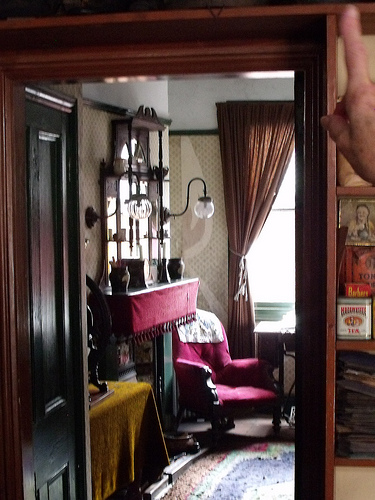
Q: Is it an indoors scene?
A: Yes, it is indoors.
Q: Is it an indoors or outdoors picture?
A: It is indoors.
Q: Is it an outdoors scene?
A: No, it is indoors.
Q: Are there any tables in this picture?
A: Yes, there is a table.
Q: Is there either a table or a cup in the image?
A: Yes, there is a table.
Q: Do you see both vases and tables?
A: Yes, there are both a table and a vase.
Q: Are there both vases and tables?
A: Yes, there are both a table and a vase.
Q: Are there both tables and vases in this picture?
A: Yes, there are both a table and a vase.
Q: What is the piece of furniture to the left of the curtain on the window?
A: The piece of furniture is a table.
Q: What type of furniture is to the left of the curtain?
A: The piece of furniture is a table.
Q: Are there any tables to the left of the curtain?
A: Yes, there is a table to the left of the curtain.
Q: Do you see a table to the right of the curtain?
A: No, the table is to the left of the curtain.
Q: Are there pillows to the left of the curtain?
A: No, there is a table to the left of the curtain.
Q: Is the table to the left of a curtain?
A: Yes, the table is to the left of a curtain.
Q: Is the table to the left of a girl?
A: No, the table is to the left of a curtain.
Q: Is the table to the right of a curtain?
A: No, the table is to the left of a curtain.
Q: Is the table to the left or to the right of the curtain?
A: The table is to the left of the curtain.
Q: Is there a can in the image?
A: No, there are no cans.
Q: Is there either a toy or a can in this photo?
A: No, there are no cans or toys.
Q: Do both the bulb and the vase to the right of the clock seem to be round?
A: Yes, both the bulb and the vase are round.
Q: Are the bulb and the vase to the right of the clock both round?
A: Yes, both the bulb and the vase are round.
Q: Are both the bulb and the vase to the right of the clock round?
A: Yes, both the bulb and the vase are round.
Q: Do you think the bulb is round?
A: Yes, the bulb is round.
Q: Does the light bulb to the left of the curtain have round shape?
A: Yes, the light bulb is round.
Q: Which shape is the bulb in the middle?
A: The light bulb is round.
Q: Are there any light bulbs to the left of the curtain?
A: Yes, there is a light bulb to the left of the curtain.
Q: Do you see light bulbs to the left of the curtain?
A: Yes, there is a light bulb to the left of the curtain.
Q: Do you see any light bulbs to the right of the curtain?
A: No, the light bulb is to the left of the curtain.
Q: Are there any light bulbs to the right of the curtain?
A: No, the light bulb is to the left of the curtain.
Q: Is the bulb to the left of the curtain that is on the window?
A: Yes, the bulb is to the left of the curtain.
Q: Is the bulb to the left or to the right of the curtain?
A: The bulb is to the left of the curtain.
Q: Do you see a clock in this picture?
A: Yes, there is a clock.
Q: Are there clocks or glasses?
A: Yes, there is a clock.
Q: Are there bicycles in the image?
A: No, there are no bicycles.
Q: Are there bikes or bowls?
A: No, there are no bikes or bowls.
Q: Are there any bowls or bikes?
A: No, there are no bikes or bowls.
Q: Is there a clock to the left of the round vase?
A: Yes, there is a clock to the left of the vase.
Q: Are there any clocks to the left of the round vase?
A: Yes, there is a clock to the left of the vase.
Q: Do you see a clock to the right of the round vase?
A: No, the clock is to the left of the vase.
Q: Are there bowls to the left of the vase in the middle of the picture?
A: No, there is a clock to the left of the vase.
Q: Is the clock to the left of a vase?
A: Yes, the clock is to the left of a vase.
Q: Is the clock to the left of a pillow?
A: No, the clock is to the left of a vase.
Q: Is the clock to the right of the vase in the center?
A: No, the clock is to the left of the vase.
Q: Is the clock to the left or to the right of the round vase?
A: The clock is to the left of the vase.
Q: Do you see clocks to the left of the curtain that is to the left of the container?
A: Yes, there is a clock to the left of the curtain.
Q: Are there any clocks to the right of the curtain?
A: No, the clock is to the left of the curtain.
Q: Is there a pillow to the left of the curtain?
A: No, there is a clock to the left of the curtain.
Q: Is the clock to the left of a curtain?
A: Yes, the clock is to the left of a curtain.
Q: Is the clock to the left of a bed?
A: No, the clock is to the left of a curtain.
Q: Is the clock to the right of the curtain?
A: No, the clock is to the left of the curtain.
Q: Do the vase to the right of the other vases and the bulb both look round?
A: Yes, both the vase and the bulb are round.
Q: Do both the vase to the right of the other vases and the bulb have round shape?
A: Yes, both the vase and the bulb are round.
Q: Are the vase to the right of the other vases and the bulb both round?
A: Yes, both the vase and the bulb are round.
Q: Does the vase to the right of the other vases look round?
A: Yes, the vase is round.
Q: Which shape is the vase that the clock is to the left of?
A: The vase is round.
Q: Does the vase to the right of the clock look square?
A: No, the vase is round.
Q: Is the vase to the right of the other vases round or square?
A: The vase is round.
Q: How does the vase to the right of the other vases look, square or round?
A: The vase is round.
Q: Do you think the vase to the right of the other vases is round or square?
A: The vase is round.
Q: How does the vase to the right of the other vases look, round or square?
A: The vase is round.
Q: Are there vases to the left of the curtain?
A: Yes, there is a vase to the left of the curtain.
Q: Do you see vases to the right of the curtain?
A: No, the vase is to the left of the curtain.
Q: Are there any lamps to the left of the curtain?
A: No, there is a vase to the left of the curtain.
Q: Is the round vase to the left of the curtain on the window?
A: Yes, the vase is to the left of the curtain.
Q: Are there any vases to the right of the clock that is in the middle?
A: Yes, there is a vase to the right of the clock.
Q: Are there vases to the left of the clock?
A: No, the vase is to the right of the clock.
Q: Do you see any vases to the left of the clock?
A: No, the vase is to the right of the clock.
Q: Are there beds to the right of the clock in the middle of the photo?
A: No, there is a vase to the right of the clock.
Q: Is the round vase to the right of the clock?
A: Yes, the vase is to the right of the clock.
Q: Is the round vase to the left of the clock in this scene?
A: No, the vase is to the right of the clock.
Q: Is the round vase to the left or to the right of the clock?
A: The vase is to the right of the clock.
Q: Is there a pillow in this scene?
A: No, there are no pillows.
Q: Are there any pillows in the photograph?
A: No, there are no pillows.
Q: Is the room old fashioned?
A: Yes, the room is old fashioned.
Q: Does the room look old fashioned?
A: Yes, the room is old fashioned.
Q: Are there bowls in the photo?
A: No, there are no bowls.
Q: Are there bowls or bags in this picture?
A: No, there are no bowls or bags.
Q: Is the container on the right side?
A: Yes, the container is on the right of the image.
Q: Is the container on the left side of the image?
A: No, the container is on the right of the image.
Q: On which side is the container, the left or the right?
A: The container is on the right of the image.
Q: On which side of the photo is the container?
A: The container is on the right of the image.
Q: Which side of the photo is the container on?
A: The container is on the right of the image.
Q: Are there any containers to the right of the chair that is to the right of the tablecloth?
A: Yes, there is a container to the right of the chair.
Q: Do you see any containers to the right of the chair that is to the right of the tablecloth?
A: Yes, there is a container to the right of the chair.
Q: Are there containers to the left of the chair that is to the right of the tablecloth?
A: No, the container is to the right of the chair.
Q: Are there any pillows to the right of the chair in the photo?
A: No, there is a container to the right of the chair.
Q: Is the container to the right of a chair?
A: Yes, the container is to the right of a chair.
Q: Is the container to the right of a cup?
A: No, the container is to the right of a chair.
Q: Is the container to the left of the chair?
A: No, the container is to the right of the chair.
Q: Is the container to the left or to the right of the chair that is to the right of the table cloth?
A: The container is to the right of the chair.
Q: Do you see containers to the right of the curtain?
A: Yes, there is a container to the right of the curtain.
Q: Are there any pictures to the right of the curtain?
A: No, there is a container to the right of the curtain.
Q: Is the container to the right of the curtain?
A: Yes, the container is to the right of the curtain.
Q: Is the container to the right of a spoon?
A: No, the container is to the right of the curtain.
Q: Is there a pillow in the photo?
A: No, there are no pillows.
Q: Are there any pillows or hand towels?
A: No, there are no pillows or hand towels.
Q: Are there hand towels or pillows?
A: No, there are no pillows or hand towels.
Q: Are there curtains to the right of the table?
A: Yes, there is a curtain to the right of the table.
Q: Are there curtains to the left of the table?
A: No, the curtain is to the right of the table.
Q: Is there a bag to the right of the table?
A: No, there is a curtain to the right of the table.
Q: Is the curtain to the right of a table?
A: Yes, the curtain is to the right of a table.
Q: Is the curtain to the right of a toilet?
A: No, the curtain is to the right of a table.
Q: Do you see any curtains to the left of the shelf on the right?
A: Yes, there is a curtain to the left of the shelf.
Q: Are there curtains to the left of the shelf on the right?
A: Yes, there is a curtain to the left of the shelf.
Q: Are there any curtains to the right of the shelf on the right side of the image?
A: No, the curtain is to the left of the shelf.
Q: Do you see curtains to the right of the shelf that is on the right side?
A: No, the curtain is to the left of the shelf.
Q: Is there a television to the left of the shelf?
A: No, there is a curtain to the left of the shelf.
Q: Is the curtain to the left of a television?
A: No, the curtain is to the left of a shelf.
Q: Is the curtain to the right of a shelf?
A: No, the curtain is to the left of a shelf.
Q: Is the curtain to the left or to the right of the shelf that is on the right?
A: The curtain is to the left of the shelf.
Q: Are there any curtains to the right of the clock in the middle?
A: Yes, there is a curtain to the right of the clock.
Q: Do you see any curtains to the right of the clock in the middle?
A: Yes, there is a curtain to the right of the clock.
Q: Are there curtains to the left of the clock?
A: No, the curtain is to the right of the clock.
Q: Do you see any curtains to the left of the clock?
A: No, the curtain is to the right of the clock.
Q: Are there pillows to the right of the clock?
A: No, there is a curtain to the right of the clock.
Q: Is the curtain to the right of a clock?
A: Yes, the curtain is to the right of a clock.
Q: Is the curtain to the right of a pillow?
A: No, the curtain is to the right of a clock.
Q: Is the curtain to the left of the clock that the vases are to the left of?
A: No, the curtain is to the right of the clock.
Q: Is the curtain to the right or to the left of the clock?
A: The curtain is to the right of the clock.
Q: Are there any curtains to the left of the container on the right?
A: Yes, there is a curtain to the left of the container.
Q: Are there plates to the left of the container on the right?
A: No, there is a curtain to the left of the container.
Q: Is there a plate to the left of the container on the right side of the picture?
A: No, there is a curtain to the left of the container.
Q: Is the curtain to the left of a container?
A: Yes, the curtain is to the left of a container.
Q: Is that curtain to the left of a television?
A: No, the curtain is to the left of a container.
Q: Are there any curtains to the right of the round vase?
A: Yes, there is a curtain to the right of the vase.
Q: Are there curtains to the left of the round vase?
A: No, the curtain is to the right of the vase.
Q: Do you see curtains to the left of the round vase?
A: No, the curtain is to the right of the vase.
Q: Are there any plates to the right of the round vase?
A: No, there is a curtain to the right of the vase.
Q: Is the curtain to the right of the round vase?
A: Yes, the curtain is to the right of the vase.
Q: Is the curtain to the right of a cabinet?
A: No, the curtain is to the right of the vase.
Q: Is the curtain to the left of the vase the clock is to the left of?
A: No, the curtain is to the right of the vase.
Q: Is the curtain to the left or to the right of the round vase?
A: The curtain is to the right of the vase.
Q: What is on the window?
A: The curtain is on the window.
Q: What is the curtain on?
A: The curtain is on the window.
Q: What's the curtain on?
A: The curtain is on the window.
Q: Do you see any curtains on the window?
A: Yes, there is a curtain on the window.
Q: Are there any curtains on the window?
A: Yes, there is a curtain on the window.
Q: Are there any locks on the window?
A: No, there is a curtain on the window.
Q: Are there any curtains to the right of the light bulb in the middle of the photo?
A: Yes, there is a curtain to the right of the bulb.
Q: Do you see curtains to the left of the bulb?
A: No, the curtain is to the right of the bulb.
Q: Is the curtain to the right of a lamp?
A: No, the curtain is to the right of the bulb.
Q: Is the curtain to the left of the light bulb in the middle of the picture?
A: No, the curtain is to the right of the light bulb.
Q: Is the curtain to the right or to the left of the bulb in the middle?
A: The curtain is to the right of the light bulb.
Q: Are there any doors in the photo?
A: Yes, there is a door.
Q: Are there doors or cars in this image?
A: Yes, there is a door.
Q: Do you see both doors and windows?
A: Yes, there are both a door and windows.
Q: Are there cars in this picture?
A: No, there are no cars.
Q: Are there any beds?
A: No, there are no beds.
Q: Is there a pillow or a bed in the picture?
A: No, there are no beds or pillows.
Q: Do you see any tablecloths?
A: Yes, there is a tablecloth.